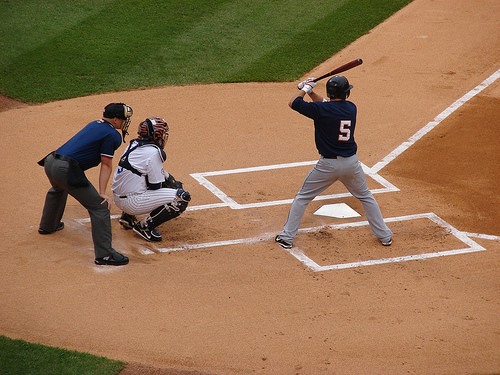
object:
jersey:
[291, 96, 357, 158]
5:
[338, 120, 351, 141]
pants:
[279, 152, 394, 247]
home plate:
[311, 200, 362, 219]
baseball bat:
[297, 59, 366, 91]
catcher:
[111, 116, 192, 241]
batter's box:
[287, 211, 486, 273]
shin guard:
[148, 204, 182, 230]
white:
[116, 173, 141, 192]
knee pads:
[175, 188, 192, 213]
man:
[38, 102, 133, 266]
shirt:
[56, 120, 121, 172]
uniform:
[279, 96, 393, 247]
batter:
[272, 75, 395, 249]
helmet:
[326, 74, 354, 97]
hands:
[301, 79, 317, 94]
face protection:
[120, 105, 134, 143]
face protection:
[162, 128, 170, 150]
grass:
[0, 336, 123, 375]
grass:
[1, 1, 407, 105]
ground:
[2, 0, 500, 374]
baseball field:
[0, 0, 498, 373]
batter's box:
[190, 153, 401, 209]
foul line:
[370, 68, 499, 172]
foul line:
[462, 230, 499, 242]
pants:
[37, 151, 113, 259]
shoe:
[275, 233, 293, 249]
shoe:
[381, 234, 392, 246]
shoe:
[118, 210, 138, 230]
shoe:
[132, 220, 164, 242]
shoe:
[35, 220, 66, 235]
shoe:
[94, 250, 130, 266]